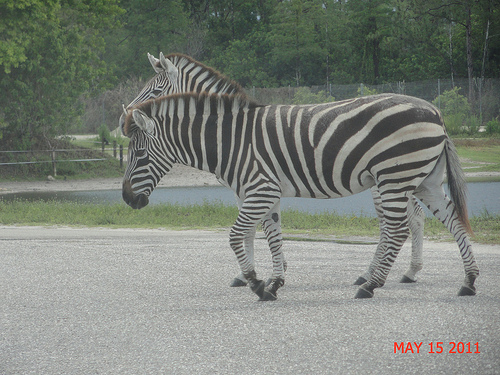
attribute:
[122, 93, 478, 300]
zebra — white, black, stripped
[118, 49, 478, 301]
zebra — white, black, stripped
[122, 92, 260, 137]
mane — brown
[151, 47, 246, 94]
mane — brown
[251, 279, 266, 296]
hoof — black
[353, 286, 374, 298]
hoof — black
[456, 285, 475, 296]
hoof — black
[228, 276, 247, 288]
hoof — black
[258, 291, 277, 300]
hoof — black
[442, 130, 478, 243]
tail — long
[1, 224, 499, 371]
pavement — grey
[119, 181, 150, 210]
nose — black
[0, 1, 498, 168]
trees — green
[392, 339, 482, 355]
date — may, red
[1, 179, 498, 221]
water — pool, blue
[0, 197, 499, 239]
grass — green